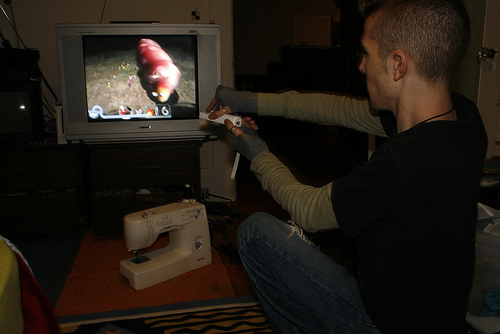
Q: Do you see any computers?
A: Yes, there is a computer.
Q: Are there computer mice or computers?
A: Yes, there is a computer.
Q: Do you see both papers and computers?
A: No, there is a computer but no papers.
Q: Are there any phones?
A: No, there are no phones.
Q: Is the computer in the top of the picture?
A: Yes, the computer is in the top of the image.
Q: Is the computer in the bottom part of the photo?
A: No, the computer is in the top of the image.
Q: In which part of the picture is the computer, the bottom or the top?
A: The computer is in the top of the image.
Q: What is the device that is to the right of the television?
A: The device is a computer.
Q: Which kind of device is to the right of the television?
A: The device is a computer.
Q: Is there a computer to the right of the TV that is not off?
A: Yes, there is a computer to the right of the TV.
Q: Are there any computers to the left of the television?
A: No, the computer is to the right of the television.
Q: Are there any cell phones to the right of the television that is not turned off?
A: No, there is a computer to the right of the TV.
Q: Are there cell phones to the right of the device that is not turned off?
A: No, there is a computer to the right of the TV.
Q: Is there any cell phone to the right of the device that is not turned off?
A: No, there is a computer to the right of the TV.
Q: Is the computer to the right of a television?
A: Yes, the computer is to the right of a television.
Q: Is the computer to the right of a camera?
A: No, the computer is to the right of a television.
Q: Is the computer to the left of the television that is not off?
A: No, the computer is to the right of the television.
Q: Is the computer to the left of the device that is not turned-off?
A: No, the computer is to the right of the television.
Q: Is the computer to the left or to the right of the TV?
A: The computer is to the right of the TV.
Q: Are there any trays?
A: No, there are no trays.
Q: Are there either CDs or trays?
A: No, there are no trays or cds.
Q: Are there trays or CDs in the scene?
A: No, there are no trays or cds.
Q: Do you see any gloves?
A: Yes, there are gloves.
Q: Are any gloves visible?
A: Yes, there are gloves.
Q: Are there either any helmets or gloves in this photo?
A: Yes, there are gloves.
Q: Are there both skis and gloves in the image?
A: No, there are gloves but no skis.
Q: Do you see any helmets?
A: No, there are no helmets.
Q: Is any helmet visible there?
A: No, there are no helmets.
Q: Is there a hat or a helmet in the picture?
A: No, there are no helmets or hats.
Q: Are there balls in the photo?
A: No, there are no balls.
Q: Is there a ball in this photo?
A: No, there are no balls.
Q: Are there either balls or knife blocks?
A: No, there are no balls or knife blocks.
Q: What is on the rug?
A: The machine is on the rug.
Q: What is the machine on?
A: The machine is on the rug.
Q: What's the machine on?
A: The machine is on the rug.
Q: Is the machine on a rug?
A: Yes, the machine is on a rug.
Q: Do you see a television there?
A: Yes, there is a television.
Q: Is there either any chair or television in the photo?
A: Yes, there is a television.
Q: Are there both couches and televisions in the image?
A: No, there is a television but no couches.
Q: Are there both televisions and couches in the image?
A: No, there is a television but no couches.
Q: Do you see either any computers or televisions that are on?
A: Yes, the television is on.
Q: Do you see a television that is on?
A: Yes, there is a television that is on.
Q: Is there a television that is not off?
A: Yes, there is a television that is on.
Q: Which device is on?
A: The device is a television.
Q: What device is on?
A: The device is a television.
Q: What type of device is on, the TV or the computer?
A: The TV is on.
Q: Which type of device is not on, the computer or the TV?
A: The computer is not on.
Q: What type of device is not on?
A: The device is a computer.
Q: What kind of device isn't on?
A: The device is a computer.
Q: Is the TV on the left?
A: Yes, the TV is on the left of the image.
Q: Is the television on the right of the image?
A: No, the television is on the left of the image.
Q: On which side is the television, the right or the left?
A: The television is on the left of the image.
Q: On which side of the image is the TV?
A: The TV is on the left of the image.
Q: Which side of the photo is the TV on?
A: The TV is on the left of the image.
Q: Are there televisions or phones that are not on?
A: No, there is a television but it is on.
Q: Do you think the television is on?
A: Yes, the television is on.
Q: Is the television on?
A: Yes, the television is on.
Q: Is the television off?
A: No, the television is on.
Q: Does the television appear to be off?
A: No, the television is on.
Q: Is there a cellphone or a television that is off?
A: No, there is a television but it is on.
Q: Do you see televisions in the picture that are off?
A: No, there is a television but it is on.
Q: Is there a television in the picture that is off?
A: No, there is a television but it is on.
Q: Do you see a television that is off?
A: No, there is a television but it is on.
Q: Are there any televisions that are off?
A: No, there is a television but it is on.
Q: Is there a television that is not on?
A: No, there is a television but it is on.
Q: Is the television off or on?
A: The television is on.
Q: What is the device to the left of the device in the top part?
A: The device is a television.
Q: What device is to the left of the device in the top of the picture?
A: The device is a television.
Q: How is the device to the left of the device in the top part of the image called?
A: The device is a television.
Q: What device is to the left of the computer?
A: The device is a television.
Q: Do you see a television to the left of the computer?
A: Yes, there is a television to the left of the computer.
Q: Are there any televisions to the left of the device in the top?
A: Yes, there is a television to the left of the computer.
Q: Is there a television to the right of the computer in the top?
A: No, the television is to the left of the computer.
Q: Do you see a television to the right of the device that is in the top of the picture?
A: No, the television is to the left of the computer.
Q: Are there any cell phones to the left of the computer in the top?
A: No, there is a television to the left of the computer.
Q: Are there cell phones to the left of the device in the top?
A: No, there is a television to the left of the computer.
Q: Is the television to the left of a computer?
A: Yes, the television is to the left of a computer.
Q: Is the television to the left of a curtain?
A: No, the television is to the left of a computer.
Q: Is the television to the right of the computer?
A: No, the television is to the left of the computer.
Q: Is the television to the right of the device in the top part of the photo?
A: No, the television is to the left of the computer.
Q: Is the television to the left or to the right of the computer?
A: The television is to the left of the computer.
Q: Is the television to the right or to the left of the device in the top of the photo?
A: The television is to the left of the computer.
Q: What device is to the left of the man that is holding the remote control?
A: The device is a television.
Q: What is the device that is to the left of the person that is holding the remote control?
A: The device is a television.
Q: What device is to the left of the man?
A: The device is a television.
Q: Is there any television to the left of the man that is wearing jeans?
A: Yes, there is a television to the left of the man.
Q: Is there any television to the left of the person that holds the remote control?
A: Yes, there is a television to the left of the man.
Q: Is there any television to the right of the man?
A: No, the television is to the left of the man.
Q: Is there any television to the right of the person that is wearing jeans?
A: No, the television is to the left of the man.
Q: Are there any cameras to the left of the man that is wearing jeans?
A: No, there is a television to the left of the man.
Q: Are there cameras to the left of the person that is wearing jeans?
A: No, there is a television to the left of the man.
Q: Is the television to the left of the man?
A: Yes, the television is to the left of the man.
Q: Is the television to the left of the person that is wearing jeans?
A: Yes, the television is to the left of the man.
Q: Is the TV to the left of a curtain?
A: No, the TV is to the left of the man.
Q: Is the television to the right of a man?
A: No, the television is to the left of a man.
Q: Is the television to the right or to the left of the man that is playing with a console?
A: The television is to the left of the man.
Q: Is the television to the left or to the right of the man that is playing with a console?
A: The television is to the left of the man.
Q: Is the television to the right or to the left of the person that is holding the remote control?
A: The television is to the left of the man.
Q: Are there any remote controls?
A: Yes, there is a remote control.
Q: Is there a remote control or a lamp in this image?
A: Yes, there is a remote control.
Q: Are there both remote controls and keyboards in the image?
A: No, there is a remote control but no keyboards.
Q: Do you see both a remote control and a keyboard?
A: No, there is a remote control but no keyboards.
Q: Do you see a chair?
A: No, there are no chairs.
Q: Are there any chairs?
A: No, there are no chairs.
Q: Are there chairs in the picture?
A: No, there are no chairs.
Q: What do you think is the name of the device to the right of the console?
A: The device is a remote control.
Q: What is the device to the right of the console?
A: The device is a remote control.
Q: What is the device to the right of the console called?
A: The device is a remote control.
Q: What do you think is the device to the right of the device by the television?
A: The device is a remote control.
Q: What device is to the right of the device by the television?
A: The device is a remote control.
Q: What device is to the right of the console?
A: The device is a remote control.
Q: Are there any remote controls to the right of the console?
A: Yes, there is a remote control to the right of the console.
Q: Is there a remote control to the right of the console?
A: Yes, there is a remote control to the right of the console.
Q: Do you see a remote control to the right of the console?
A: Yes, there is a remote control to the right of the console.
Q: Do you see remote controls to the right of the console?
A: Yes, there is a remote control to the right of the console.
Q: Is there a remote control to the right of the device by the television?
A: Yes, there is a remote control to the right of the console.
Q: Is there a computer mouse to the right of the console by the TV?
A: No, there is a remote control to the right of the console.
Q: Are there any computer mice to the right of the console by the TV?
A: No, there is a remote control to the right of the console.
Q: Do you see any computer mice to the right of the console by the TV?
A: No, there is a remote control to the right of the console.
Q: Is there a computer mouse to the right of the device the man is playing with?
A: No, there is a remote control to the right of the console.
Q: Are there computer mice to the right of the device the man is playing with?
A: No, there is a remote control to the right of the console.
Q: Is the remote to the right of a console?
A: Yes, the remote is to the right of a console.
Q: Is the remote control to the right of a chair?
A: No, the remote control is to the right of a console.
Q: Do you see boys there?
A: No, there are no boys.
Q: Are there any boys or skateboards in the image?
A: No, there are no boys or skateboards.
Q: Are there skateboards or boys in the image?
A: No, there are no boys or skateboards.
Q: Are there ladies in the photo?
A: No, there are no ladies.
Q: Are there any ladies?
A: No, there are no ladies.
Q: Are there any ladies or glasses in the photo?
A: No, there are no ladies or glasses.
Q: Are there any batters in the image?
A: No, there are no batters.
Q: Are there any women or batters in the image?
A: No, there are no batters or women.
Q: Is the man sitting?
A: Yes, the man is sitting.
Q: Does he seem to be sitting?
A: Yes, the man is sitting.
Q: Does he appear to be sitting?
A: Yes, the man is sitting.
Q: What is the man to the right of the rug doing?
A: The man is sitting.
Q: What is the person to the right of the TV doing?
A: The man is sitting.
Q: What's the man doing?
A: The man is sitting.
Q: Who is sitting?
A: The man is sitting.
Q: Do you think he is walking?
A: No, the man is sitting.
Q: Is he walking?
A: No, the man is sitting.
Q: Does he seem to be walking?
A: No, the man is sitting.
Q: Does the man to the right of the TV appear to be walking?
A: No, the man is sitting.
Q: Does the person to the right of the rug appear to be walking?
A: No, the man is sitting.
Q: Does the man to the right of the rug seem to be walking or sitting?
A: The man is sitting.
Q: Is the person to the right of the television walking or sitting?
A: The man is sitting.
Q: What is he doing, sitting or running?
A: The man is sitting.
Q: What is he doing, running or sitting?
A: The man is sitting.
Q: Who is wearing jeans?
A: The man is wearing jeans.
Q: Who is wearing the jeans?
A: The man is wearing jeans.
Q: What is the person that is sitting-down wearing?
A: The man is wearing jeans.